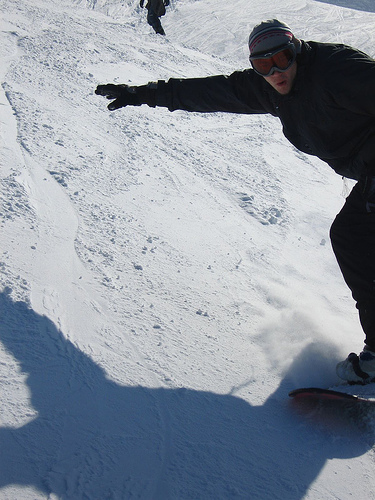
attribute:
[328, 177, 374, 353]
pants — black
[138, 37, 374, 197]
jacket — black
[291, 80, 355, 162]
jacket — black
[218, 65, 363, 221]
clothing — black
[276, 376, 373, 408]
rim — black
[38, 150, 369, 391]
snow — white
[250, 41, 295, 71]
goggles — red and gray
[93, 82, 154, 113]
glove — black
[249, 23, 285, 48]
stripe — black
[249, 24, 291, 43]
stripe — white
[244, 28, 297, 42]
stripe — red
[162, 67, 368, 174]
jacket — black